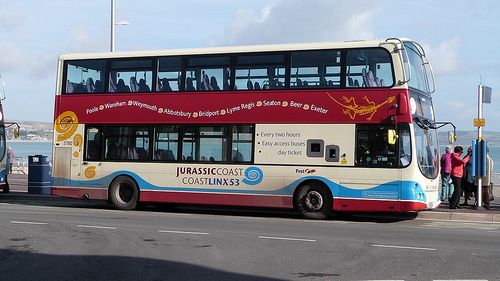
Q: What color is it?
A: Red.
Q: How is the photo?
A: Clear.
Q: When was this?
A: Daytime.